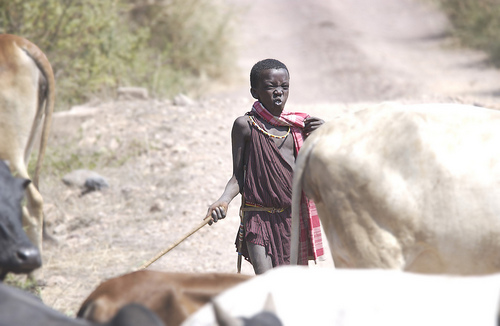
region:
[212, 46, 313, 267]
Child wearing dark clothes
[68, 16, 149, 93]
Green grass with brown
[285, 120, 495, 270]
White animal with tail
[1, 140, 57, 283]
Black cow following looking at camera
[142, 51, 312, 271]
Child carrying a stick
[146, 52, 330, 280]
Child carrying a stick keeping herd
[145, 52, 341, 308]
Child carrying a a brown stick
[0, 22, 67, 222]
Beige cow with tail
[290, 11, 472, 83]
Rocky road for passage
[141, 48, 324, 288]
Child wearing red and white scarf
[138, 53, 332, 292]
A child herding cow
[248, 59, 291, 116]
the boy is making a face.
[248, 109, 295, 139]
necklace around the boy's neck.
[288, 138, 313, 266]
tail of a white cow standing in front of the boy.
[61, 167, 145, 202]
small pile of rocks in the background.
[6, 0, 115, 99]
clump of green bushes behind the cow.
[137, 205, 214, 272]
the boy is holding a rod.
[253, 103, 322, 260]
the boy is wearing a pink scarf.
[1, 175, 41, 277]
the face of the cow on the far left.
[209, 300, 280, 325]
the horns on the cow in the front.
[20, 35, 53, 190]
the tail of the cow on the far left.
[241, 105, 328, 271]
pink scarf around the neck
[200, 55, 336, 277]
kid walking on the dirt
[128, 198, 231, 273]
fingers wrapped around a stick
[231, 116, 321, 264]
purple fabric draped around the body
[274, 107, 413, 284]
backside of a white animal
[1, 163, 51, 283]
part of an animal's face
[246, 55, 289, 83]
black hair on the head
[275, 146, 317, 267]
tail hanging off the back of the body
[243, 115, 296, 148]
necklace around the neck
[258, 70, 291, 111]
face is scrunched up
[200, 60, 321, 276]
a boy with a scarf around his neck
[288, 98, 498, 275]
a white cow facing right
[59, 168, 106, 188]
a gray rock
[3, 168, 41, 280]
a black faced cow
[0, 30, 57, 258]
a tan and brown cow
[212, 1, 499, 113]
a dirt road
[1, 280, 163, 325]
a gray colored cow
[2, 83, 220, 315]
rocks on a dirt road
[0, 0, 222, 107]
tall green grass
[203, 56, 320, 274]
a boy making a face